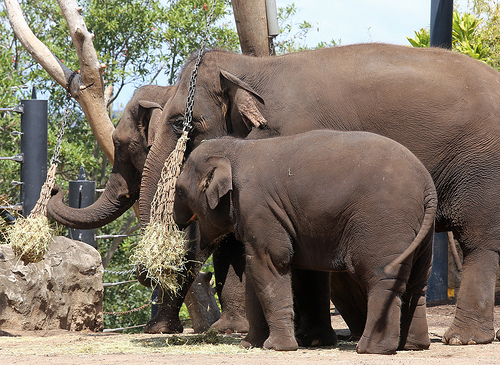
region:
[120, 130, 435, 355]
Baby elephant eating hay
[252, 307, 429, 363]
The baby elephant has four legs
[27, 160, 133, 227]
The elephant is using its trunk to eat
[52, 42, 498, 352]
A family of elephants are eating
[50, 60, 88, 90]
There is a chain wrapped around the tree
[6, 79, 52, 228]
A fence post is attached to the fence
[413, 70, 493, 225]
The elephant has wrinkles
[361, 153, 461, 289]
Baby elephants tail is curved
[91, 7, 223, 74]
Tall trees are in the background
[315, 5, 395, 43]
The sky is blue with no clouds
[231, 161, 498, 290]
the elephant has tail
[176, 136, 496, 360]
the elephant has tail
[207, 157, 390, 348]
the elephant has tail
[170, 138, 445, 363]
juvenile elephant eating hay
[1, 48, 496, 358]
three elephants eating hay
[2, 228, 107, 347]
brown boulder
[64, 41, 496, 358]
two adult elephants and one juvenile elephant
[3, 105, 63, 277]
hanging ball of hay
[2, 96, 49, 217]
fence with a black post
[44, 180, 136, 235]
trunk of an elephant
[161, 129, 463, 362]
young elephant eating food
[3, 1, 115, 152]
branch of a tree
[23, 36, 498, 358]
three elephants near a fence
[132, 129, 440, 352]
a baby elephant eating hay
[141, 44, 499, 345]
the largest elephant of three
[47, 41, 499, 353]
three big grey elephants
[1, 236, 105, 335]
a giant rock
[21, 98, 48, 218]
a large metal pole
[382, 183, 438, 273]
a young elephant's tail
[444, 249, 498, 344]
an elephant's left rear leg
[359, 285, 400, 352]
a baby elephant's left rear leg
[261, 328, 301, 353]
a baby elephant's left front foot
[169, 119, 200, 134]
an elephant's left eye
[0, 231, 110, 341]
A large rock.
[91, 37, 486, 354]
A group of three elephants.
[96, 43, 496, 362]
The elephants are brown.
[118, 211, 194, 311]
The elephants are eating hay.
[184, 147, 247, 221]
The elephants have small ears.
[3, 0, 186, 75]
Trees are in the background.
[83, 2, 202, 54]
The trees are green.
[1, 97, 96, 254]
A black fence is in the background.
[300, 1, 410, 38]
The sky is blue.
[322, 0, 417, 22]
The sky is clear.